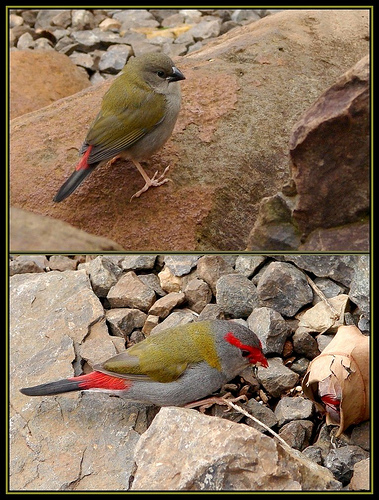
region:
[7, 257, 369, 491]
Rocks below the bird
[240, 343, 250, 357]
The right eye of the bird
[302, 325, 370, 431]
An item near the bird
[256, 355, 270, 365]
The beak fo the bird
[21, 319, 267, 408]
A bird on the rocks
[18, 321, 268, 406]
The bird is multicolored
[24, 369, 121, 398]
The tail of the bird is red and black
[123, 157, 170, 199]
The right leg of the bird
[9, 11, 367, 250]
A large stone below the bird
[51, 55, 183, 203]
A bird on a stone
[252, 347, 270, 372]
bird with red beak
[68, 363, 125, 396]
red tail feather on bird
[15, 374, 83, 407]
gray tail feather on bird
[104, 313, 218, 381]
bird with yellow wing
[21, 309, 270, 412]
bird with yellow red and gray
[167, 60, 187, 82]
black beak on bird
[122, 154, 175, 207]
brown foot of bird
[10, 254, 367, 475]
brown and gray rocks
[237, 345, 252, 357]
dark colored eye of bird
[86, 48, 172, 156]
gray and green bird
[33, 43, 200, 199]
a bird sitting on a rock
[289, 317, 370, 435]
a bird inside of a dead leaf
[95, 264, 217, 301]
many small brown and grey rocks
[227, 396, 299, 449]
a long piece of grass sticking out of the rocks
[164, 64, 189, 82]
black beak of the bird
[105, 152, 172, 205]
yellow legs and feet of the bird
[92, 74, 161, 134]
green feathered wings of the bird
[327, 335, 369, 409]
a dead rolled up tan leaf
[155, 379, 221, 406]
grey feathered belly of the bird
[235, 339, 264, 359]
black eyes of the bird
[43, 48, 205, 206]
green bird on a rock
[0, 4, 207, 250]
green bird on an orange rock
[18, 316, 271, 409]
grey and green bird with red on tail and head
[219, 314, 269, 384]
red on bird's face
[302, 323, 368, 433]
trash in front of bird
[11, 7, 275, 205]
pebbles behind green bird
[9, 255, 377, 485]
pebbles behind and in front of bird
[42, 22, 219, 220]
green bird standing on rock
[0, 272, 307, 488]
bird standing on tan rock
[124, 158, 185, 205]
green bird's leg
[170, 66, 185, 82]
the black beak on a bird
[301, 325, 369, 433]
an old dry leaf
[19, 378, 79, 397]
a black tail of a bird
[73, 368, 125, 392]
red feather's on a bird's tail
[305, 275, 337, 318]
a twig in the rocks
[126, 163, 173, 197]
the foot of a bird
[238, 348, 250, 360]
the black eye of a bird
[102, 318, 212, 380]
green feathers on a bird's back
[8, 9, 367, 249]
a large rock under a bird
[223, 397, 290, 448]
a dry piece of grass